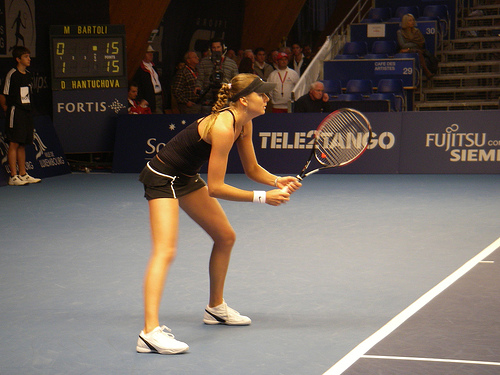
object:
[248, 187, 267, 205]
wrist band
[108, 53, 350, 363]
player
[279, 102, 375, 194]
racket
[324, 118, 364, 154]
netting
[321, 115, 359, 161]
logo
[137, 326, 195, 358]
shoe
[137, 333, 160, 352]
stripe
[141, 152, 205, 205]
shorts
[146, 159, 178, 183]
stripe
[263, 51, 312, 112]
man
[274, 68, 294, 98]
lanyard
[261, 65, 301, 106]
sweater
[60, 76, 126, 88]
writing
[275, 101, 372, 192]
tennis racket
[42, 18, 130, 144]
scoreboard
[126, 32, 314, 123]
spectators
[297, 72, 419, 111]
seats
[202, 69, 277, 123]
hair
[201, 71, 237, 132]
braid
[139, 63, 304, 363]
woman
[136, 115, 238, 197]
uniform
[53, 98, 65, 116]
letter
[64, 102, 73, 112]
letter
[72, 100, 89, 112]
letter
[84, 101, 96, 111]
letter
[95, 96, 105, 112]
letter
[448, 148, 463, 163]
letter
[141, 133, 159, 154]
letter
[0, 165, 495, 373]
court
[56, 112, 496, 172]
sign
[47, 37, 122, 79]
score chart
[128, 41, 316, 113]
people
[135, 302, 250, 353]
shoes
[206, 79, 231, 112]
ponytail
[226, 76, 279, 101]
sunvisor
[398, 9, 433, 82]
woman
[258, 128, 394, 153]
letters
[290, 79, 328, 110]
man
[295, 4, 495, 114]
stands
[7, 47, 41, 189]
ball boy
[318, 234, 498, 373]
line